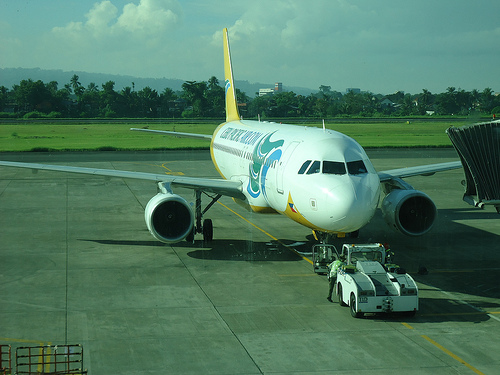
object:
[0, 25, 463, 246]
airplane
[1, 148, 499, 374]
tarmac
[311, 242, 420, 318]
vehicle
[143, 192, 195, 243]
jet engine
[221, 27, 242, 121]
tail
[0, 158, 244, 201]
wing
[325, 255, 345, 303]
driver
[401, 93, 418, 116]
tree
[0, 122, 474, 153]
area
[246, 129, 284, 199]
logo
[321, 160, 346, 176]
window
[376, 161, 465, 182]
wing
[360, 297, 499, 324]
shadow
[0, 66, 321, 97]
mountain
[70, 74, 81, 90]
tree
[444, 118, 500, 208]
passenger bridge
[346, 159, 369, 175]
window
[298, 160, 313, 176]
cockpit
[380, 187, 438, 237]
jet engine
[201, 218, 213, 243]
wheel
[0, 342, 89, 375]
luggage cart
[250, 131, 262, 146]
lettering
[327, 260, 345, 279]
shirt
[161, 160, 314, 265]
line